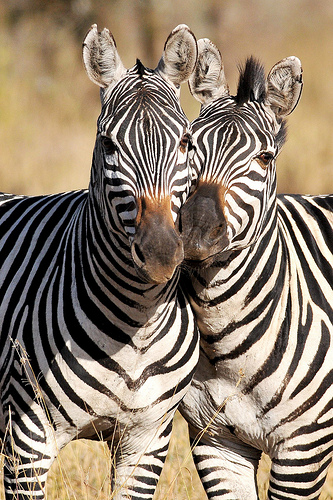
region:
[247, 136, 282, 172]
The eye of a zebra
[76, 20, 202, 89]
the ears of a zebra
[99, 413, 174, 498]
the leg of a zebra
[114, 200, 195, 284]
the nose of a zebra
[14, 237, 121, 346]
the stripes of a zebra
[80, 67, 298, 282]
two zebra heads close together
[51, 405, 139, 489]
grass below a zebra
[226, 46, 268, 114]
the hair at the top of the head of a zebra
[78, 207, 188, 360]
the neck of a zebra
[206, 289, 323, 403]
the torso of a zebra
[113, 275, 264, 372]
THe zebras are visible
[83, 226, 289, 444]
THe zebras are visible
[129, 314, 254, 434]
THe zebras are visible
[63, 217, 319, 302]
THe zebras are visible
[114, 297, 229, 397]
THe zebras are visible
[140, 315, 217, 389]
The zebras are visible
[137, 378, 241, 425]
The zebras are visible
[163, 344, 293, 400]
The zebras are visible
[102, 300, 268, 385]
The zebras are visible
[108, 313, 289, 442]
The zebras are visible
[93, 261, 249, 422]
The zebras are visible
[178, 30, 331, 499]
black and white striped zebra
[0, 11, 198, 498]
black and white striped zebra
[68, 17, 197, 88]
pair of zebra ears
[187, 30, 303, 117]
pair of zebra ears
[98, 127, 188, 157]
dark brown zebra eyes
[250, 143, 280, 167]
eye of a zebra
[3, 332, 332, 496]
dry tan colored grass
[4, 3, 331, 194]
blurry background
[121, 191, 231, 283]
black coloured zebra noses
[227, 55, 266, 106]
furry black zebra mane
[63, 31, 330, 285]
two zebra's faces together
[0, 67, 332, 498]
two zebra's standing together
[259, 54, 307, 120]
a right ear of a zebra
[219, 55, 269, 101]
black mane of hair of zebra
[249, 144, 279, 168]
a right eye of a zebra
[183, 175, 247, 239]
a nose of a zebra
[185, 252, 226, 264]
a mouth of a zebra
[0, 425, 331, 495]
legs of two zebras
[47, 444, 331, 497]
dead grass in background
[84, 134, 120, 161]
left eye of a zebra